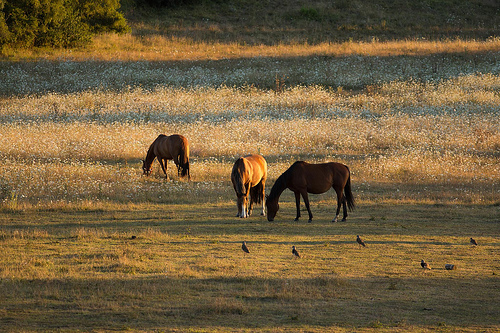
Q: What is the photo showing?
A: It is showing a field.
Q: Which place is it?
A: It is a field.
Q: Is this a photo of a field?
A: Yes, it is showing a field.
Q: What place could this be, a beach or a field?
A: It is a field.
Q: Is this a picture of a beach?
A: No, the picture is showing a field.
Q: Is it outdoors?
A: Yes, it is outdoors.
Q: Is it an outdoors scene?
A: Yes, it is outdoors.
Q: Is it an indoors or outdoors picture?
A: It is outdoors.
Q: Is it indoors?
A: No, it is outdoors.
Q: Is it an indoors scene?
A: No, it is outdoors.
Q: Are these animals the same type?
A: No, there are both horses and birds.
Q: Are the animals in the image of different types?
A: Yes, they are horses and birds.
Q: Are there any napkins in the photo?
A: No, there are no napkins.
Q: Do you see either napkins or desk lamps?
A: No, there are no napkins or desk lamps.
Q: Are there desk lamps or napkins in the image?
A: No, there are no napkins or desk lamps.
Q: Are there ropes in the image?
A: No, there are no ropes.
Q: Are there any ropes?
A: No, there are no ropes.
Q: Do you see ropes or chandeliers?
A: No, there are no ropes or chandeliers.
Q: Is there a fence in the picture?
A: No, there are no fences.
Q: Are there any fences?
A: No, there are no fences.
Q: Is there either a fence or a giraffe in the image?
A: No, there are no fences or giraffes.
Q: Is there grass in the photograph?
A: Yes, there is grass.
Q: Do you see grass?
A: Yes, there is grass.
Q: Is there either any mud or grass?
A: Yes, there is grass.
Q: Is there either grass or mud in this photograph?
A: Yes, there is grass.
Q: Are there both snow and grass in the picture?
A: No, there is grass but no snow.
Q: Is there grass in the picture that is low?
A: Yes, there is low grass.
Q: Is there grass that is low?
A: Yes, there is grass that is low.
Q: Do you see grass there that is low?
A: Yes, there is grass that is low.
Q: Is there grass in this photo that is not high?
A: Yes, there is low grass.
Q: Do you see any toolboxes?
A: No, there are no toolboxes.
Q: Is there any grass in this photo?
A: Yes, there is grass.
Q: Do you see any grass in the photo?
A: Yes, there is grass.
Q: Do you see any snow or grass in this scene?
A: Yes, there is grass.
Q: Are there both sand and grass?
A: No, there is grass but no sand.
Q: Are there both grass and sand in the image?
A: No, there is grass but no sand.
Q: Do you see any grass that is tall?
A: Yes, there is tall grass.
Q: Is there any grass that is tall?
A: Yes, there is grass that is tall.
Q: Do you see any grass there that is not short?
A: Yes, there is tall grass.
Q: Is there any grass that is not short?
A: Yes, there is tall grass.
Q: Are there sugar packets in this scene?
A: No, there are no sugar packets.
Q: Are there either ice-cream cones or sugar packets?
A: No, there are no sugar packets or ice-cream cones.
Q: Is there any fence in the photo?
A: No, there are no fences.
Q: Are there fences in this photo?
A: No, there are no fences.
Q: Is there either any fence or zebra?
A: No, there are no fences or zebras.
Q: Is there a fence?
A: No, there are no fences.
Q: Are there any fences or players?
A: No, there are no fences or players.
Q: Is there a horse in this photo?
A: Yes, there is a horse.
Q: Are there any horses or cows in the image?
A: Yes, there is a horse.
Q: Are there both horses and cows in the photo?
A: No, there is a horse but no cows.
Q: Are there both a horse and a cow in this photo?
A: No, there is a horse but no cows.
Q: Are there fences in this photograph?
A: No, there are no fences.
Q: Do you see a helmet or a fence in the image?
A: No, there are no fences or helmets.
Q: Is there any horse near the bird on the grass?
A: Yes, there is a horse near the bird.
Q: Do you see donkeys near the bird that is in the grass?
A: No, there is a horse near the bird.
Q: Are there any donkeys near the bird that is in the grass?
A: No, there is a horse near the bird.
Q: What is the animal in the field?
A: The animal is a horse.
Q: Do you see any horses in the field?
A: Yes, there is a horse in the field.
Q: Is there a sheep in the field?
A: No, there is a horse in the field.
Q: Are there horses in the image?
A: Yes, there is a horse.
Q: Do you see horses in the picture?
A: Yes, there is a horse.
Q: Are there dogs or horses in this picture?
A: Yes, there is a horse.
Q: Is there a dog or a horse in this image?
A: Yes, there is a horse.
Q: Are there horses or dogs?
A: Yes, there is a horse.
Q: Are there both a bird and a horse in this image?
A: Yes, there are both a horse and a bird.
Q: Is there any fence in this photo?
A: No, there are no fences.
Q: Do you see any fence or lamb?
A: No, there are no fences or lambs.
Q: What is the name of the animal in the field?
A: The animal is a horse.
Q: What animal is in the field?
A: The animal is a horse.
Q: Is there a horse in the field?
A: Yes, there is a horse in the field.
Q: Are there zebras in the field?
A: No, there is a horse in the field.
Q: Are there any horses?
A: Yes, there is a horse.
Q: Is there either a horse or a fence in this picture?
A: Yes, there is a horse.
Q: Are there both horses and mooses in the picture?
A: No, there is a horse but no mooses.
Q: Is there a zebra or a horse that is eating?
A: Yes, the horse is eating.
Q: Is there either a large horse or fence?
A: Yes, there is a large horse.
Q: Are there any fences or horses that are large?
A: Yes, the horse is large.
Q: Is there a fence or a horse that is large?
A: Yes, the horse is large.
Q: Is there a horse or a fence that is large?
A: Yes, the horse is large.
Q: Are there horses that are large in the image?
A: Yes, there is a large horse.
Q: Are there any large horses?
A: Yes, there is a large horse.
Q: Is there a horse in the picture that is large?
A: Yes, there is a horse that is large.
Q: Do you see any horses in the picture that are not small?
A: Yes, there is a large horse.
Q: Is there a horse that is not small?
A: Yes, there is a large horse.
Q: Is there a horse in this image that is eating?
A: Yes, there is a horse that is eating.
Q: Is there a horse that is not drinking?
A: Yes, there is a horse that is eating.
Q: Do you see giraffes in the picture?
A: No, there are no giraffes.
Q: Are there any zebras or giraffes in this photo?
A: No, there are no giraffes or zebras.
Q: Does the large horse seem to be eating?
A: Yes, the horse is eating.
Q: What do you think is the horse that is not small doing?
A: The horse is eating.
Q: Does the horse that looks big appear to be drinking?
A: No, the horse is eating.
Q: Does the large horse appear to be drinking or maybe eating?
A: The horse is eating.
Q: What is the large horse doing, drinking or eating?
A: The horse is eating.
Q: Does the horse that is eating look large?
A: Yes, the horse is large.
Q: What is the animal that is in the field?
A: The animal is a horse.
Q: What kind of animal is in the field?
A: The animal is a horse.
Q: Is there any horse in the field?
A: Yes, there is a horse in the field.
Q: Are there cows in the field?
A: No, there is a horse in the field.